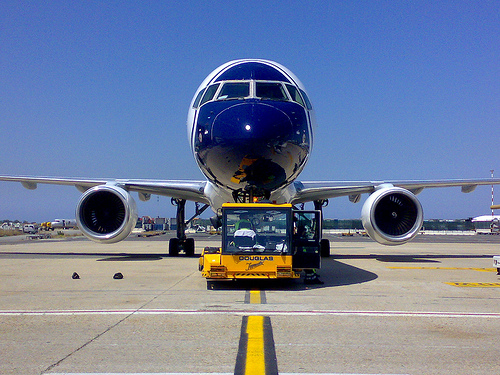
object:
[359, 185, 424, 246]
engine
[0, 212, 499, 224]
horizon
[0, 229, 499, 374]
field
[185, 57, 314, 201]
front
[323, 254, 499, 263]
shadow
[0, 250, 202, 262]
shadow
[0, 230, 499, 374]
concrete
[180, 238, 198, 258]
rear-landing wheels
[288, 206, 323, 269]
door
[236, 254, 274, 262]
name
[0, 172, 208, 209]
wing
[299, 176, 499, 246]
wing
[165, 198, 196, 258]
landing gear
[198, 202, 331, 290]
vehicle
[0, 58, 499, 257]
jet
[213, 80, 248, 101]
windshield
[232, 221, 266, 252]
person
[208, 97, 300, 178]
nose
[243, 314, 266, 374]
markings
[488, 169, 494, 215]
radio antennae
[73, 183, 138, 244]
engine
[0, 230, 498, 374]
tarmac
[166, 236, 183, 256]
wheel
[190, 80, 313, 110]
cockpit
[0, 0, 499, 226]
sky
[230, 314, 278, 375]
stripe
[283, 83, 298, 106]
window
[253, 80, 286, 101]
window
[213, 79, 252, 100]
window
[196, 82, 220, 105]
window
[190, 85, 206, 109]
window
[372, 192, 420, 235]
turbine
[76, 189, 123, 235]
turbine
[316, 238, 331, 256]
wheel